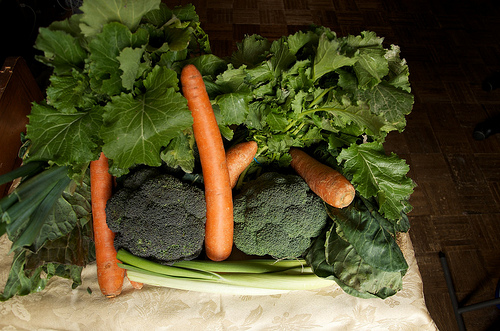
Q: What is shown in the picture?
A: Vegetables.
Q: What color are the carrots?
A: Orange.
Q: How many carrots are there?
A: Four.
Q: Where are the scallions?
A: In front of the broccoli.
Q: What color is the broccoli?
A: Green.